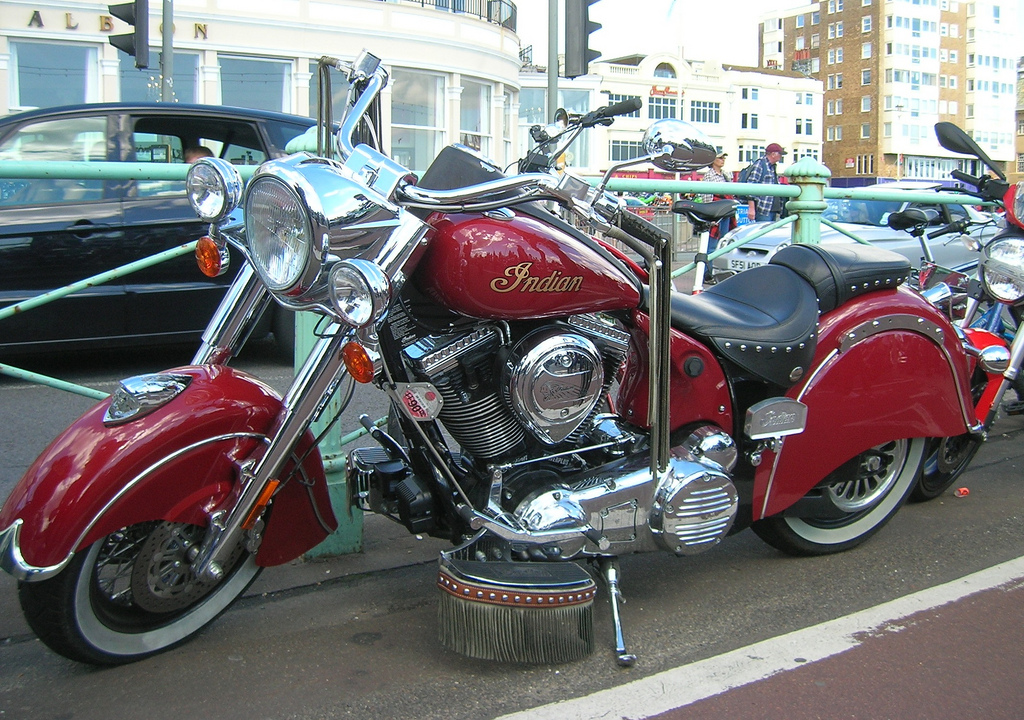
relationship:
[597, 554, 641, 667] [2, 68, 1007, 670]
kick stand on a bike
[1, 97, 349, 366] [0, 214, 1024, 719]
car on side of pavement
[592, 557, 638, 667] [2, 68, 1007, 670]
kick stand on bike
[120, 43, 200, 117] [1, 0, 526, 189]
window on building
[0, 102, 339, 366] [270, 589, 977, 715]
car on road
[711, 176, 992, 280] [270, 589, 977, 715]
vehicles on road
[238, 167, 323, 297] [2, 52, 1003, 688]
headlight on bike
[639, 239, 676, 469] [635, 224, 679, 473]
tassels on handlebars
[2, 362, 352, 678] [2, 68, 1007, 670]
wheelon on bike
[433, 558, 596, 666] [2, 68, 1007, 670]
foot rest on bike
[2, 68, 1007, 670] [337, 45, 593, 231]
bike has handle bar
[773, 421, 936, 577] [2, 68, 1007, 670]
wheel on bike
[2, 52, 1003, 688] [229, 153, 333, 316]
bike has light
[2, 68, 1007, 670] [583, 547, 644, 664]
bike has a kick stand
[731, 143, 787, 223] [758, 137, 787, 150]
man wearing a baseball cap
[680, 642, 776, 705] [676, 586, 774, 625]
line marking pavement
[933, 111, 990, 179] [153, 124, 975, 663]
mirror on side of bike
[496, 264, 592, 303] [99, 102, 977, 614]
letters are on motorcycle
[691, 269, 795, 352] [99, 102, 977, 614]
seat on motorcycle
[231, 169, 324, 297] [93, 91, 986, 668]
headlight on motorcycle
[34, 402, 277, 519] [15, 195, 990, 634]
fender on motorcycle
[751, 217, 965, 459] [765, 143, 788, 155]
man wearing a baseball cap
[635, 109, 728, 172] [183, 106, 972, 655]
rearview mirror on a motorcycle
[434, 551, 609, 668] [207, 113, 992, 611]
foot rest on a motorcycle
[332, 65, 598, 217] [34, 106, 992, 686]
handle bars are on a motorcycle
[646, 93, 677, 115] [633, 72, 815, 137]
window on a building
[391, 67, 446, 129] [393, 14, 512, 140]
window on a building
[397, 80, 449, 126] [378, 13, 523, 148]
window on a building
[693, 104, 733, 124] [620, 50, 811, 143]
window on a building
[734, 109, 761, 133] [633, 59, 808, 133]
window on a building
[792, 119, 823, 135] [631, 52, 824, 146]
window on a building